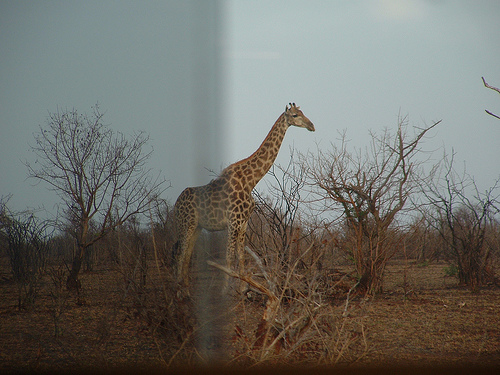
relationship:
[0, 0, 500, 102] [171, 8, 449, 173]
cloud in sky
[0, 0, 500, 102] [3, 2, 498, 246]
cloud in sky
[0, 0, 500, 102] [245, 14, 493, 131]
cloud in sky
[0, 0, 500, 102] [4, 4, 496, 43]
cloud in sky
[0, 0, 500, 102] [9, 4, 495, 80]
cloud in sky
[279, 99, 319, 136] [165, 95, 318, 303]
head on giraffe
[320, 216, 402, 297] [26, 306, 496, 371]
bushes on ground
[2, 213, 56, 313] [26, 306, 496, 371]
bushes on ground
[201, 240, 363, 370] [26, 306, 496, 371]
bushes on ground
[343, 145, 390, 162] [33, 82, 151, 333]
leaves on tree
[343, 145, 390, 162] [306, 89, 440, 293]
leaves on tree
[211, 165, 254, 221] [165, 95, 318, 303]
pattern on giraffe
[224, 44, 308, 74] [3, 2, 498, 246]
cloud in sky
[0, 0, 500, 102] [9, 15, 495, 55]
cloud in sky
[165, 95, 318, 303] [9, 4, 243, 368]
giraffe seen through window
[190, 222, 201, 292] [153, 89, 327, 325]
hind leg belonging to giraffe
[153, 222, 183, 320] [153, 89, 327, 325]
hind leg belonging to giraffe